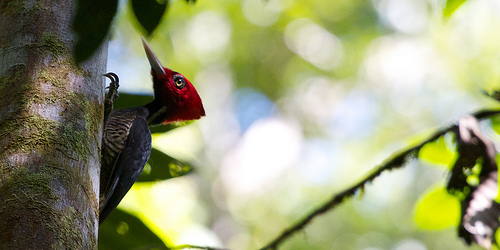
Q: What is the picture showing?
A: A woodpecker.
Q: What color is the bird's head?
A: Red.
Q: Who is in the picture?
A: A bird.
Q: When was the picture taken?
A: During the day.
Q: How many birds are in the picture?
A: One.